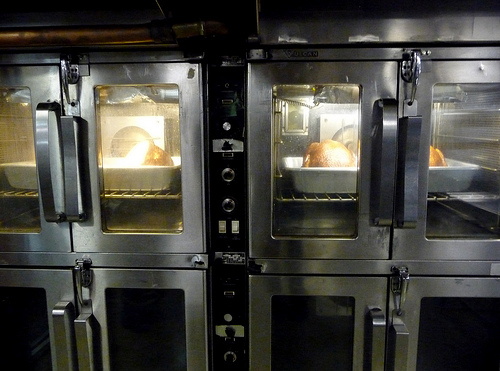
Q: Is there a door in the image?
A: Yes, there are doors.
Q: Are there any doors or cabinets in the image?
A: Yes, there are doors.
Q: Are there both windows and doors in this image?
A: Yes, there are both doors and windows.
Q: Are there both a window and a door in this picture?
A: Yes, there are both a door and a window.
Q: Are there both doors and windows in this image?
A: Yes, there are both doors and windows.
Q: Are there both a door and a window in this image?
A: Yes, there are both a door and a window.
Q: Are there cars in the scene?
A: No, there are no cars.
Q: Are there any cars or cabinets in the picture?
A: No, there are no cars or cabinets.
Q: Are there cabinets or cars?
A: No, there are no cars or cabinets.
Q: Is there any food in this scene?
A: Yes, there is food.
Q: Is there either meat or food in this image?
A: Yes, there is food.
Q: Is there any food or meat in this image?
A: Yes, there is food.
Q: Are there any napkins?
A: No, there are no napkins.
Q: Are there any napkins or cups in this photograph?
A: No, there are no napkins or cups.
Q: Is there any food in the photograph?
A: Yes, there is food.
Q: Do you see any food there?
A: Yes, there is food.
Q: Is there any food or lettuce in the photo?
A: Yes, there is food.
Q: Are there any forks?
A: No, there are no forks.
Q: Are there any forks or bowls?
A: No, there are no forks or bowls.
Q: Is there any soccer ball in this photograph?
A: No, there are no soccer balls.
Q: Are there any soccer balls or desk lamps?
A: No, there are no soccer balls or desk lamps.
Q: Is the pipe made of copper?
A: Yes, the pipe is made of copper.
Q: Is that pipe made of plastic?
A: No, the pipe is made of copper.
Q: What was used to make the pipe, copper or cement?
A: The pipe is made of copper.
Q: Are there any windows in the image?
A: Yes, there is a window.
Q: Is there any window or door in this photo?
A: Yes, there is a window.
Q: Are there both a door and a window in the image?
A: Yes, there are both a window and a door.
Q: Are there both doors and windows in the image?
A: Yes, there are both a window and a door.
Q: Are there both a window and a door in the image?
A: Yes, there are both a window and a door.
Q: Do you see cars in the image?
A: No, there are no cars.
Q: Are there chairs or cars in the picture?
A: No, there are no cars or chairs.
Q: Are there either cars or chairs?
A: No, there are no cars or chairs.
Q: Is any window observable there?
A: Yes, there is a window.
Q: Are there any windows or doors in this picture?
A: Yes, there is a window.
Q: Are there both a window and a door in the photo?
A: Yes, there are both a window and a door.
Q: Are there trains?
A: No, there are no trains.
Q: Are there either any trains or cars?
A: No, there are no trains or cars.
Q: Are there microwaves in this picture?
A: No, there are no microwaves.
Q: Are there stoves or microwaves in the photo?
A: No, there are no microwaves or stoves.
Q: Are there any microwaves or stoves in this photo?
A: No, there are no microwaves or stoves.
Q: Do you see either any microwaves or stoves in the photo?
A: No, there are no microwaves or stoves.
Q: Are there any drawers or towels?
A: No, there are no drawers or towels.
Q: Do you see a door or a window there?
A: Yes, there are doors.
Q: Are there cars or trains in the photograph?
A: No, there are no trains or cars.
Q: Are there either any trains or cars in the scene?
A: No, there are no trains or cars.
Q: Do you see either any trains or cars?
A: No, there are no trains or cars.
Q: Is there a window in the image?
A: Yes, there is a window.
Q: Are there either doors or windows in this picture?
A: Yes, there is a window.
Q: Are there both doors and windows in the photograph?
A: Yes, there are both a window and a door.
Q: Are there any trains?
A: No, there are no trains.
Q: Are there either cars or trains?
A: No, there are no trains or cars.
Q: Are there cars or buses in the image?
A: No, there are no cars or buses.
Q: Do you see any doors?
A: Yes, there are doors.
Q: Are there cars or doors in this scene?
A: Yes, there are doors.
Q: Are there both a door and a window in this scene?
A: Yes, there are both a door and a window.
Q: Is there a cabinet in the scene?
A: No, there are no cabinets.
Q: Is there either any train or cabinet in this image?
A: No, there are no cabinets or trains.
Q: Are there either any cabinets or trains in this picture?
A: No, there are no cabinets or trains.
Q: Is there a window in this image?
A: Yes, there is a window.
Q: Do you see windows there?
A: Yes, there is a window.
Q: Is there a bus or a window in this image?
A: Yes, there is a window.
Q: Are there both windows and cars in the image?
A: No, there is a window but no cars.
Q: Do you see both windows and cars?
A: No, there is a window but no cars.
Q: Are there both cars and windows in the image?
A: No, there is a window but no cars.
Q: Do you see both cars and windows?
A: No, there is a window but no cars.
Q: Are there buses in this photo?
A: No, there are no buses.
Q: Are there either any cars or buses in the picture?
A: No, there are no buses or cars.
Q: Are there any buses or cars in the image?
A: No, there are no buses or cars.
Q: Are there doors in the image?
A: Yes, there is a door.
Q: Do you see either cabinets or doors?
A: Yes, there is a door.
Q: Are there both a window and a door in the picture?
A: Yes, there are both a door and a window.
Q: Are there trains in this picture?
A: No, there are no trains.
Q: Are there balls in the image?
A: No, there are no balls.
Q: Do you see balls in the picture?
A: No, there are no balls.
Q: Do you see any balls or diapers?
A: No, there are no balls or diapers.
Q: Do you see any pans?
A: Yes, there is a pan.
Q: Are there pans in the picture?
A: Yes, there is a pan.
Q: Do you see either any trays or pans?
A: Yes, there is a pan.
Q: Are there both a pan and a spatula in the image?
A: No, there is a pan but no spatulas.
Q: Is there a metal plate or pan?
A: Yes, there is a metal pan.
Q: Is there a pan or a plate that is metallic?
A: Yes, the pan is metallic.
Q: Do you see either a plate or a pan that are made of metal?
A: Yes, the pan is made of metal.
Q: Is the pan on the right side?
A: Yes, the pan is on the right of the image.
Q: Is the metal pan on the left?
A: No, the pan is on the right of the image.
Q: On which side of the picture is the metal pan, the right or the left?
A: The pan is on the right of the image.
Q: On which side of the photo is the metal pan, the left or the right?
A: The pan is on the right of the image.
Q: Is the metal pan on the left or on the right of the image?
A: The pan is on the right of the image.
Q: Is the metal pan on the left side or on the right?
A: The pan is on the right of the image.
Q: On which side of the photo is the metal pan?
A: The pan is on the right of the image.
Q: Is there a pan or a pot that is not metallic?
A: No, there is a pan but it is metallic.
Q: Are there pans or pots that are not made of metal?
A: No, there is a pan but it is made of metal.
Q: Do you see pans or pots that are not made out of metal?
A: No, there is a pan but it is made of metal.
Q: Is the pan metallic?
A: Yes, the pan is metallic.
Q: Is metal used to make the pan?
A: Yes, the pan is made of metal.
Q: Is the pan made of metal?
A: Yes, the pan is made of metal.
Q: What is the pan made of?
A: The pan is made of metal.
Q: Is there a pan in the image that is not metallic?
A: No, there is a pan but it is metallic.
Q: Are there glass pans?
A: No, there is a pan but it is made of metal.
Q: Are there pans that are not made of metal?
A: No, there is a pan but it is made of metal.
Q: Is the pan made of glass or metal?
A: The pan is made of metal.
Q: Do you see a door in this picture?
A: Yes, there are doors.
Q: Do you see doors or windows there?
A: Yes, there are doors.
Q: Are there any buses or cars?
A: No, there are no cars or buses.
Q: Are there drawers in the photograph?
A: No, there are no drawers.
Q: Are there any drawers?
A: No, there are no drawers.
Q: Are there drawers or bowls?
A: No, there are no drawers or bowls.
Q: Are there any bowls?
A: No, there are no bowls.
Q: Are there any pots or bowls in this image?
A: No, there are no bowls or pots.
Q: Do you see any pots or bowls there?
A: No, there are no bowls or pots.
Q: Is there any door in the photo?
A: Yes, there are doors.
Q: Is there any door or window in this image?
A: Yes, there are doors.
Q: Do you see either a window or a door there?
A: Yes, there are doors.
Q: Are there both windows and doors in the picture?
A: Yes, there are both doors and windows.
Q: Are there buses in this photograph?
A: No, there are no buses.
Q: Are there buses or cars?
A: No, there are no buses or cars.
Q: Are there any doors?
A: Yes, there are doors.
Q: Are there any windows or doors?
A: Yes, there are doors.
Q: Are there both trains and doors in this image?
A: No, there are doors but no trains.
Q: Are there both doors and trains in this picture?
A: No, there are doors but no trains.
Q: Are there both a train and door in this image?
A: No, there are doors but no trains.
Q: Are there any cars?
A: No, there are no cars.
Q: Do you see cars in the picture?
A: No, there are no cars.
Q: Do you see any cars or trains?
A: No, there are no cars or trains.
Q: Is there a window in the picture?
A: Yes, there is a window.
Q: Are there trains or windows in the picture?
A: Yes, there is a window.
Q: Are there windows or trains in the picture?
A: Yes, there is a window.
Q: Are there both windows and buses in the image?
A: No, there is a window but no buses.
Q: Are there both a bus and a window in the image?
A: No, there is a window but no buses.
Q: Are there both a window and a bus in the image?
A: No, there is a window but no buses.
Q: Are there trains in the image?
A: No, there are no trains.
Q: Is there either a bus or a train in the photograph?
A: No, there are no trains or buses.